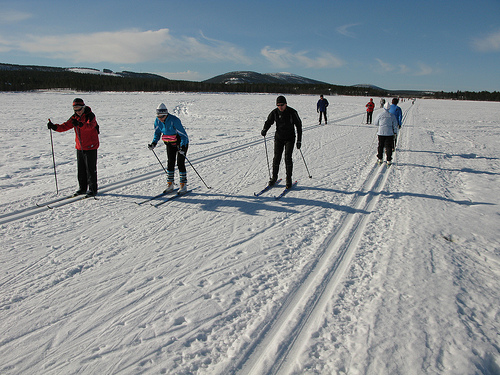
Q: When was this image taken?
A: During the day.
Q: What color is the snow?
A: White.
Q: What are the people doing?
A: Skiing.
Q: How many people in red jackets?
A: Two.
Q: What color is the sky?
A: Blue.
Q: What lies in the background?
A: Mountains.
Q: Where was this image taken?
A: Snow area.